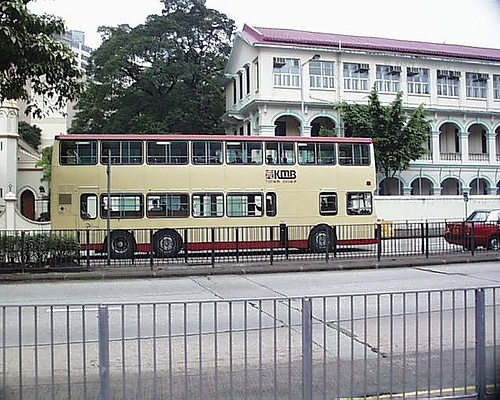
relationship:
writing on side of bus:
[262, 167, 298, 185] [48, 135, 379, 267]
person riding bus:
[265, 154, 276, 163] [48, 135, 379, 267]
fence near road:
[1, 216, 496, 275] [379, 223, 458, 255]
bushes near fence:
[0, 232, 82, 270] [1, 216, 496, 275]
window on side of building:
[273, 58, 300, 74] [218, 18, 499, 197]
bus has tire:
[48, 135, 379, 267] [307, 222, 338, 256]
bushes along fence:
[0, 232, 82, 270] [1, 216, 496, 275]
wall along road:
[373, 194, 498, 230] [379, 223, 458, 255]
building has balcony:
[218, 18, 499, 197] [466, 83, 488, 99]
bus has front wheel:
[48, 135, 379, 267] [105, 227, 134, 260]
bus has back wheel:
[48, 135, 379, 267] [307, 222, 338, 256]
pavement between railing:
[0, 257, 498, 400] [0, 282, 497, 399]